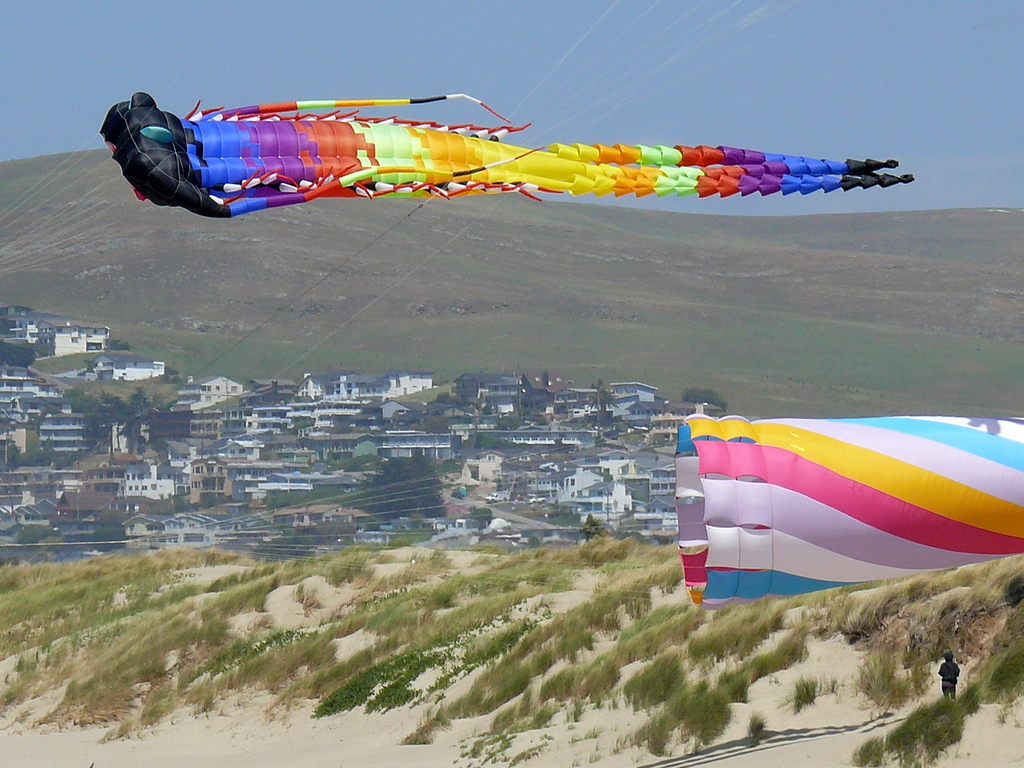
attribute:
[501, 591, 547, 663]
grass —  long, green and yellow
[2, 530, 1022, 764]
grass — long, green, yellow, tall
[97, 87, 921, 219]
wind sock — rainbow colored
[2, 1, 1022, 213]
sky — blue, clear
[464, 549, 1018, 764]
hill — rolling, green, brown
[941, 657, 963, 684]
shirt — black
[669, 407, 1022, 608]
windsock — pastel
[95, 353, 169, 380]
house — white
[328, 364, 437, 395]
house — large, white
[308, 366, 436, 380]
roof — dark, gray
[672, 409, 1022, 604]
balloon — multi colored